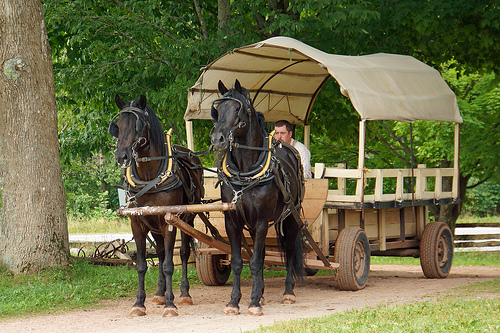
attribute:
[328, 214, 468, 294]
wheels — black, brown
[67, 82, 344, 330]
horses — in photo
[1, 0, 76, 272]
tree — brown, tall, large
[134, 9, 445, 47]
trees — green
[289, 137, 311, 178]
shirt — white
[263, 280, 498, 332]
grass — green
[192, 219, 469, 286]
tires — dusty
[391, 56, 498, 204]
tree — lush, green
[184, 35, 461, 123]
canopy — cream colored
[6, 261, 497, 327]
path — dirt